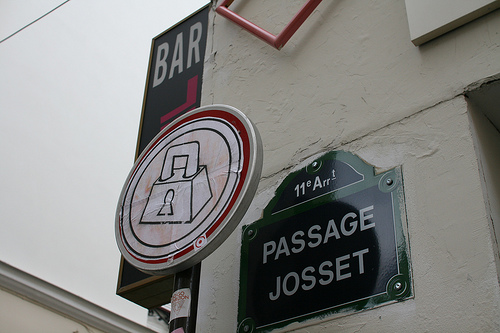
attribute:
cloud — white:
[3, 5, 209, 331]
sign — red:
[114, 104, 264, 276]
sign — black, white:
[138, 0, 216, 160]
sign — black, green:
[239, 150, 427, 331]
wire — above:
[0, 0, 71, 46]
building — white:
[193, 1, 500, 331]